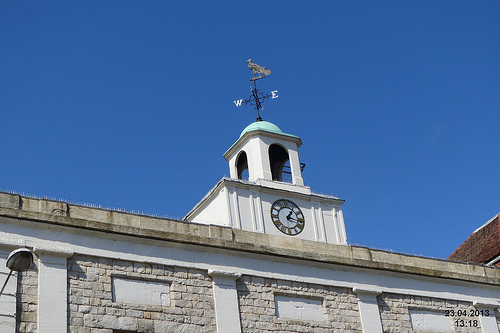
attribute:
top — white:
[192, 93, 328, 245]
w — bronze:
[231, 96, 242, 108]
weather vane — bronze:
[233, 63, 279, 122]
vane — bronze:
[229, 59, 285, 116]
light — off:
[5, 245, 37, 273]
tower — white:
[178, 119, 372, 250]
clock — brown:
[268, 199, 305, 235]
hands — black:
[285, 210, 292, 216]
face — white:
[263, 193, 322, 239]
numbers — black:
[269, 201, 305, 235]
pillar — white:
[209, 271, 243, 331]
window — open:
[233, 126, 323, 204]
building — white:
[2, 180, 499, 330]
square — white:
[275, 290, 334, 326]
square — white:
[110, 271, 174, 304]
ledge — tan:
[1, 185, 496, 281]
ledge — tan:
[217, 172, 350, 207]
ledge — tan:
[172, 172, 224, 217]